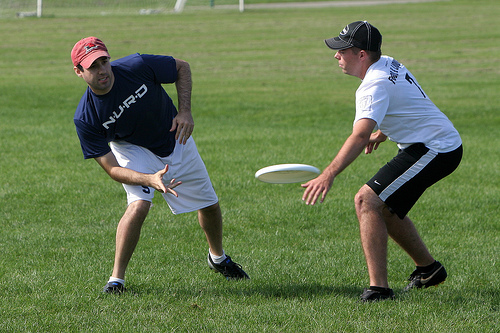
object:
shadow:
[123, 280, 404, 303]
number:
[404, 72, 427, 101]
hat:
[68, 35, 111, 68]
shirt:
[71, 52, 178, 160]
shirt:
[354, 55, 464, 153]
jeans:
[361, 282, 400, 291]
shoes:
[402, 261, 448, 294]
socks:
[416, 260, 437, 273]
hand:
[149, 163, 182, 197]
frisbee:
[252, 163, 318, 185]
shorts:
[365, 143, 463, 221]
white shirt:
[352, 55, 463, 155]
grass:
[2, 4, 497, 331]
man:
[68, 35, 250, 299]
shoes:
[358, 287, 394, 303]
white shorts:
[106, 136, 221, 217]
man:
[300, 19, 461, 302]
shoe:
[207, 253, 249, 280]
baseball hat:
[325, 20, 382, 52]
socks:
[106, 277, 124, 285]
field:
[0, 2, 498, 332]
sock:
[208, 246, 228, 265]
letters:
[98, 85, 154, 131]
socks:
[370, 286, 388, 292]